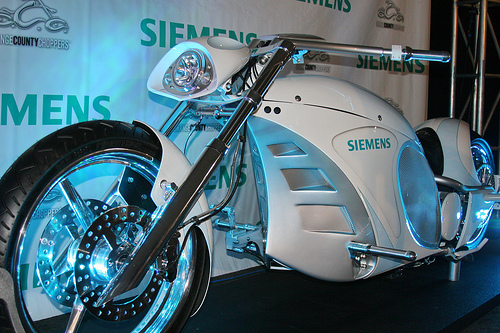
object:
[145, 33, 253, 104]
headlight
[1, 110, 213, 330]
front wheel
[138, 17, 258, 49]
logo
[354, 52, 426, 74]
logo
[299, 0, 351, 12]
logo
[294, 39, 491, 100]
handlebars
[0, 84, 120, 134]
logo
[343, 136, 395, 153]
logo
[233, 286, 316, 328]
floor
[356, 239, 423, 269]
pedal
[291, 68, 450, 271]
tank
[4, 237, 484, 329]
platform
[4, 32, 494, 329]
bike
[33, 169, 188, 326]
spokes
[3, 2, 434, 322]
wall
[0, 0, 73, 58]
emblem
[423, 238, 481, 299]
stand